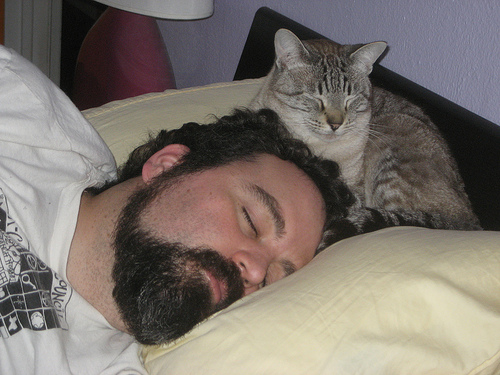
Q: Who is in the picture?
A: A man.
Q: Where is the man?
A: In bed.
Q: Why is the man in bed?
A: Sleeping.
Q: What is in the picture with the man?
A: A cat.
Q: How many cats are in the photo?
A: One.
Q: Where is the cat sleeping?
A: On the pillow.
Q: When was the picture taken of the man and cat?
A: Morning.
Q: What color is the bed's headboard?
A: Black.